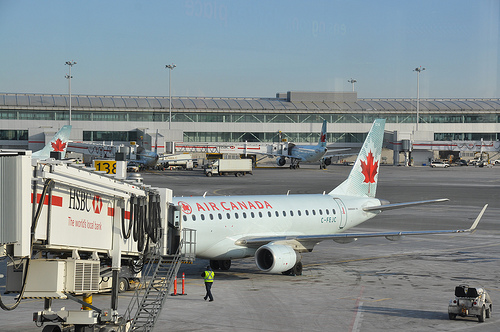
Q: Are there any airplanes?
A: Yes, there is an airplane.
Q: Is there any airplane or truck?
A: Yes, there is an airplane.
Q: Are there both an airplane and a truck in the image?
A: Yes, there are both an airplane and a truck.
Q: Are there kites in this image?
A: No, there are no kites.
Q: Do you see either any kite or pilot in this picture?
A: No, there are no kites or pilots.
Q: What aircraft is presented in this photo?
A: The aircraft is an airplane.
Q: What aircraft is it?
A: The aircraft is an airplane.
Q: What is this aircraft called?
A: This is an airplane.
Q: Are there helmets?
A: No, there are no helmets.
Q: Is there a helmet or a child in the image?
A: No, there are no helmets or children.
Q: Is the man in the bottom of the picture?
A: Yes, the man is in the bottom of the image.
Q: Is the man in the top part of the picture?
A: No, the man is in the bottom of the image.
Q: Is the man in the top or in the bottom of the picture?
A: The man is in the bottom of the image.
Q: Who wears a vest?
A: The man wears a vest.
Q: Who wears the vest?
A: The man wears a vest.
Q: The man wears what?
A: The man wears a vest.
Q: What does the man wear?
A: The man wears a vest.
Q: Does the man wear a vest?
A: Yes, the man wears a vest.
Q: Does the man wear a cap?
A: No, the man wears a vest.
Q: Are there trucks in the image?
A: Yes, there is a truck.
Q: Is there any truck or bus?
A: Yes, there is a truck.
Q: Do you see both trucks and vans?
A: No, there is a truck but no vans.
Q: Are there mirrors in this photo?
A: No, there are no mirrors.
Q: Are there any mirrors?
A: No, there are no mirrors.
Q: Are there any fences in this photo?
A: No, there are no fences.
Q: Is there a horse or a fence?
A: No, there are no fences or horses.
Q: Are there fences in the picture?
A: No, there are no fences.